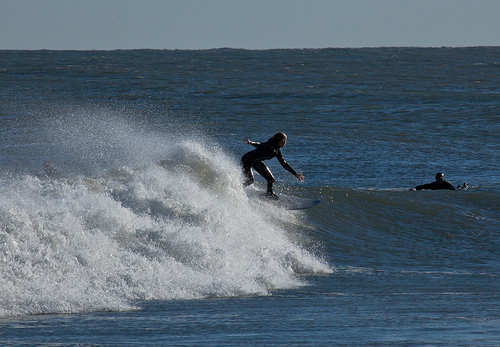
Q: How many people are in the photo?
A: 2.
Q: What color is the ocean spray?
A: White.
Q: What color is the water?
A: Blue.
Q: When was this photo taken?
A: During the day.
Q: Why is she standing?
A: She is surfing.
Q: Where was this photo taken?
A: At sea.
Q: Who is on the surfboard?
A: A woman.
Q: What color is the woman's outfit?
A: Black.